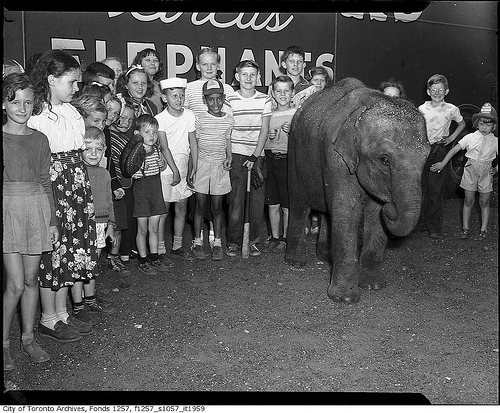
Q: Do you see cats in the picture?
A: No, there are no cats.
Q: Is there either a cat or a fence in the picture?
A: No, there are no cats or fences.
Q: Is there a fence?
A: No, there are no fences.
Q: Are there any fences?
A: No, there are no fences.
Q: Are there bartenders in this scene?
A: No, there are no bartenders.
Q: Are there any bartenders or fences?
A: No, there are no bartenders or fences.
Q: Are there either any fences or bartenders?
A: No, there are no bartenders or fences.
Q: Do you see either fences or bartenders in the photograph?
A: No, there are no bartenders or fences.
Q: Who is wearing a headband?
A: The girl is wearing a headband.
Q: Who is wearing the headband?
A: The girl is wearing a headband.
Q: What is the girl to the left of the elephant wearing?
A: The girl is wearing a hair band.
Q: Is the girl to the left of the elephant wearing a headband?
A: Yes, the girl is wearing a headband.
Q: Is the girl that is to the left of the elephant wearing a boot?
A: No, the girl is wearing a headband.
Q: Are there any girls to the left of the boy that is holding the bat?
A: Yes, there is a girl to the left of the boy.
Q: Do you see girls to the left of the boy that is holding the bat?
A: Yes, there is a girl to the left of the boy.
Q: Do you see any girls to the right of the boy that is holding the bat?
A: No, the girl is to the left of the boy.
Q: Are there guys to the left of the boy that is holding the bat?
A: No, there is a girl to the left of the boy.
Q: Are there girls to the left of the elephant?
A: Yes, there is a girl to the left of the elephant.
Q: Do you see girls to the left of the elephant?
A: Yes, there is a girl to the left of the elephant.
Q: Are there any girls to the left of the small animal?
A: Yes, there is a girl to the left of the elephant.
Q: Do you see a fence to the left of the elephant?
A: No, there is a girl to the left of the elephant.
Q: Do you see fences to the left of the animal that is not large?
A: No, there is a girl to the left of the elephant.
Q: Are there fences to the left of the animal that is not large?
A: No, there is a girl to the left of the elephant.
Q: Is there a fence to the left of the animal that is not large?
A: No, there is a girl to the left of the elephant.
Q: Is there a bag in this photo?
A: No, there are no bags.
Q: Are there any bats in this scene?
A: Yes, there is a bat.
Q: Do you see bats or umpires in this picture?
A: Yes, there is a bat.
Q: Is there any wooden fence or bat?
A: Yes, there is a wood bat.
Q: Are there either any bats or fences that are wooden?
A: Yes, the bat is wooden.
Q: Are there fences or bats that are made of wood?
A: Yes, the bat is made of wood.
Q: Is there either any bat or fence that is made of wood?
A: Yes, the bat is made of wood.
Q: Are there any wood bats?
A: Yes, there is a wood bat.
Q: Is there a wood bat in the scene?
A: Yes, there is a wood bat.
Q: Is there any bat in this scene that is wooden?
A: Yes, there is a bat that is wooden.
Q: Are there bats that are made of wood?
A: Yes, there is a bat that is made of wood.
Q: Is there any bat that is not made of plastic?
A: Yes, there is a bat that is made of wood.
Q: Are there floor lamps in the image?
A: No, there are no floor lamps.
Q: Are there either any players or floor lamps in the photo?
A: No, there are no floor lamps or players.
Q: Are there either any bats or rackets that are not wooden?
A: No, there is a bat but it is wooden.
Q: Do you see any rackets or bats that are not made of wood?
A: No, there is a bat but it is made of wood.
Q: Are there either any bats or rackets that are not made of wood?
A: No, there is a bat but it is made of wood.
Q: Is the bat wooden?
A: Yes, the bat is wooden.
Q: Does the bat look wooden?
A: Yes, the bat is wooden.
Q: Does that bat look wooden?
A: Yes, the bat is wooden.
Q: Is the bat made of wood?
A: Yes, the bat is made of wood.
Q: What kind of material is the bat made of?
A: The bat is made of wood.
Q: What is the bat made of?
A: The bat is made of wood.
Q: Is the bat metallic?
A: No, the bat is wooden.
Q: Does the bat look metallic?
A: No, the bat is wooden.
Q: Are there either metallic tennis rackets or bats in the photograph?
A: No, there is a bat but it is wooden.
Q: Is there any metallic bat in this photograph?
A: No, there is a bat but it is wooden.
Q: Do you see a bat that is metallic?
A: No, there is a bat but it is wooden.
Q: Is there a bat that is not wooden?
A: No, there is a bat but it is wooden.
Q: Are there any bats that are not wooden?
A: No, there is a bat but it is wooden.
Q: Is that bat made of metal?
A: No, the bat is made of wood.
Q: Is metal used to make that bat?
A: No, the bat is made of wood.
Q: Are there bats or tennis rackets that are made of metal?
A: No, there is a bat but it is made of wood.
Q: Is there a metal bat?
A: No, there is a bat but it is made of wood.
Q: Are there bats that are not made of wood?
A: No, there is a bat but it is made of wood.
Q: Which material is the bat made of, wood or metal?
A: The bat is made of wood.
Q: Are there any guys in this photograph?
A: No, there are no guys.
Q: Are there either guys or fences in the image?
A: No, there are no guys or fences.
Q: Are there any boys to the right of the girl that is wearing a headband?
A: Yes, there is a boy to the right of the girl.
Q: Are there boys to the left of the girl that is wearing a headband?
A: No, the boy is to the right of the girl.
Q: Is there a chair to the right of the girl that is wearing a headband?
A: No, there is a boy to the right of the girl.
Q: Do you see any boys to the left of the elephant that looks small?
A: Yes, there is a boy to the left of the elephant.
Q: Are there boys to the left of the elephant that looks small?
A: Yes, there is a boy to the left of the elephant.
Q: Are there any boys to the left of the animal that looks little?
A: Yes, there is a boy to the left of the elephant.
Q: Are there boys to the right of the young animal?
A: No, the boy is to the left of the elephant.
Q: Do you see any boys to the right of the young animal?
A: No, the boy is to the left of the elephant.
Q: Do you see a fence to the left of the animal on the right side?
A: No, there is a boy to the left of the elephant.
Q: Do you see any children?
A: Yes, there are children.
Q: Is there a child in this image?
A: Yes, there are children.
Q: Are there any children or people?
A: Yes, there are children.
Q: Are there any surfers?
A: No, there are no surfers.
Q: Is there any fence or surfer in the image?
A: No, there are no surfers or fences.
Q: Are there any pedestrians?
A: No, there are no pedestrians.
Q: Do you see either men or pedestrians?
A: No, there are no pedestrians or men.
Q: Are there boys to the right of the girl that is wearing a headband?
A: Yes, there is a boy to the right of the girl.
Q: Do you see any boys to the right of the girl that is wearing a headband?
A: Yes, there is a boy to the right of the girl.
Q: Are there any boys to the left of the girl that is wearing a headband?
A: No, the boy is to the right of the girl.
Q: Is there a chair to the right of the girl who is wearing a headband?
A: No, there is a boy to the right of the girl.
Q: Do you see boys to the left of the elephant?
A: Yes, there is a boy to the left of the elephant.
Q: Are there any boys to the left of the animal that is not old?
A: Yes, there is a boy to the left of the elephant.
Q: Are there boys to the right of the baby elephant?
A: No, the boy is to the left of the elephant.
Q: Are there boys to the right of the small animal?
A: No, the boy is to the left of the elephant.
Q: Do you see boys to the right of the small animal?
A: No, the boy is to the left of the elephant.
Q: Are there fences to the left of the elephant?
A: No, there is a boy to the left of the elephant.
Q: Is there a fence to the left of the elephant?
A: No, there is a boy to the left of the elephant.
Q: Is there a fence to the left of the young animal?
A: No, there is a boy to the left of the elephant.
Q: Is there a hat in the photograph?
A: Yes, there is a hat.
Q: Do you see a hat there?
A: Yes, there is a hat.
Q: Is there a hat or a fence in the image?
A: Yes, there is a hat.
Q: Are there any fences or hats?
A: Yes, there is a hat.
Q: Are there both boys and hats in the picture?
A: Yes, there are both a hat and a boy.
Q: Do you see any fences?
A: No, there are no fences.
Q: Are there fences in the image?
A: No, there are no fences.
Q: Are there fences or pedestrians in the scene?
A: No, there are no fences or pedestrians.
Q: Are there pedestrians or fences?
A: No, there are no fences or pedestrians.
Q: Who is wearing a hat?
A: The girl is wearing a hat.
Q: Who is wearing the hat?
A: The girl is wearing a hat.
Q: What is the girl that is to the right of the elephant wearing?
A: The girl is wearing a hat.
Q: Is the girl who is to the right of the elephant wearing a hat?
A: Yes, the girl is wearing a hat.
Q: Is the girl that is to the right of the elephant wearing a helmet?
A: No, the girl is wearing a hat.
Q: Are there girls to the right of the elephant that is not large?
A: Yes, there is a girl to the right of the elephant.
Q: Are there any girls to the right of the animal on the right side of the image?
A: Yes, there is a girl to the right of the elephant.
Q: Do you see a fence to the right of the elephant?
A: No, there is a girl to the right of the elephant.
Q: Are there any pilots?
A: No, there are no pilots.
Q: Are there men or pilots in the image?
A: No, there are no pilots or men.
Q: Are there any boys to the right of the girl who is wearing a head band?
A: Yes, there is a boy to the right of the girl.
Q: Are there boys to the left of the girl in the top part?
A: No, the boy is to the right of the girl.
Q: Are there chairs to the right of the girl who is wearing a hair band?
A: No, there is a boy to the right of the girl.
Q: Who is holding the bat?
A: The boy is holding the bat.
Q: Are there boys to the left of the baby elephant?
A: Yes, there is a boy to the left of the elephant.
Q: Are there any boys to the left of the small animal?
A: Yes, there is a boy to the left of the elephant.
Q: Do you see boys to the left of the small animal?
A: Yes, there is a boy to the left of the elephant.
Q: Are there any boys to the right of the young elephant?
A: No, the boy is to the left of the elephant.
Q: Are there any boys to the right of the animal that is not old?
A: No, the boy is to the left of the elephant.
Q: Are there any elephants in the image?
A: Yes, there is an elephant.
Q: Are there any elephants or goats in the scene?
A: Yes, there is an elephant.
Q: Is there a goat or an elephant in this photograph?
A: Yes, there is an elephant.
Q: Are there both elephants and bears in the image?
A: No, there is an elephant but no bears.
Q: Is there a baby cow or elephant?
A: Yes, there is a baby elephant.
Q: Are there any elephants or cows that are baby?
A: Yes, the elephant is a baby.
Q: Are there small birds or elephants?
A: Yes, there is a small elephant.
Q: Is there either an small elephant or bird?
A: Yes, there is a small elephant.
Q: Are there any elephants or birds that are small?
A: Yes, the elephant is small.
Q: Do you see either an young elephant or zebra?
A: Yes, there is a young elephant.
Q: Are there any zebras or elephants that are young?
A: Yes, the elephant is young.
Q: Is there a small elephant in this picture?
A: Yes, there is a small elephant.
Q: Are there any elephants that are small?
A: Yes, there is an elephant that is small.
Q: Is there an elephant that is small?
A: Yes, there is an elephant that is small.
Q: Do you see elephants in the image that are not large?
A: Yes, there is a small elephant.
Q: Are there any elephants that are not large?
A: Yes, there is a small elephant.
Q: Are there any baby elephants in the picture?
A: Yes, there is a baby elephant.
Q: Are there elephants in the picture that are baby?
A: Yes, there is an elephant that is a baby.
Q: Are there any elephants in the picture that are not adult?
A: Yes, there is an baby elephant.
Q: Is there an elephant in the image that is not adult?
A: Yes, there is an baby elephant.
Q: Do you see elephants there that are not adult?
A: Yes, there is an baby elephant.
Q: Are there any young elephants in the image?
A: Yes, there is a young elephant.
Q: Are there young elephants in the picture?
A: Yes, there is a young elephant.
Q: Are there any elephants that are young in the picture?
A: Yes, there is a young elephant.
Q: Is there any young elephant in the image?
A: Yes, there is a young elephant.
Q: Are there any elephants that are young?
A: Yes, there is an elephant that is young.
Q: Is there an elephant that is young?
A: Yes, there is an elephant that is young.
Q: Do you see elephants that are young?
A: Yes, there is an elephant that is young.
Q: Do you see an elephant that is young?
A: Yes, there is an elephant that is young.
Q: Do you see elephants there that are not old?
A: Yes, there is an young elephant.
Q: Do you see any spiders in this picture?
A: No, there are no spiders.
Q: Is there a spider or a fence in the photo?
A: No, there are no spiders or fences.